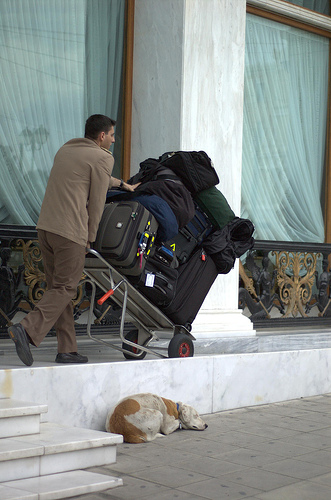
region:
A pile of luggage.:
[91, 150, 255, 332]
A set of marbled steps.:
[0, 396, 123, 498]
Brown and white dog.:
[106, 393, 209, 443]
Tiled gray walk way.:
[67, 393, 329, 498]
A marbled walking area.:
[0, 332, 330, 432]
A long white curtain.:
[238, 11, 329, 243]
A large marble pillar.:
[127, 0, 244, 218]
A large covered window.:
[0, 0, 129, 227]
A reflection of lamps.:
[15, 123, 51, 175]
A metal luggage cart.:
[79, 248, 195, 358]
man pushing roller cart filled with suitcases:
[3, 91, 262, 371]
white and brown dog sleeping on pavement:
[76, 376, 221, 451]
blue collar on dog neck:
[169, 399, 186, 432]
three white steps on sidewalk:
[0, 370, 130, 497]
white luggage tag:
[140, 267, 158, 291]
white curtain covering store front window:
[238, 7, 329, 248]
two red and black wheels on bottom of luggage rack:
[111, 323, 199, 365]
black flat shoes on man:
[3, 315, 93, 364]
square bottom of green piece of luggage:
[189, 173, 240, 236]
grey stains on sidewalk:
[211, 479, 250, 497]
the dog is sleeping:
[105, 384, 225, 467]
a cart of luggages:
[54, 102, 254, 354]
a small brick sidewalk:
[158, 430, 272, 494]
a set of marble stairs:
[11, 400, 124, 490]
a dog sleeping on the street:
[96, 392, 213, 440]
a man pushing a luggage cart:
[32, 113, 244, 373]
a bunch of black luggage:
[132, 180, 236, 302]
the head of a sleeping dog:
[171, 400, 211, 437]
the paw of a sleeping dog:
[156, 407, 187, 439]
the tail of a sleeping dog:
[127, 430, 163, 454]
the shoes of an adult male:
[11, 311, 98, 370]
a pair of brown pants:
[16, 213, 103, 355]